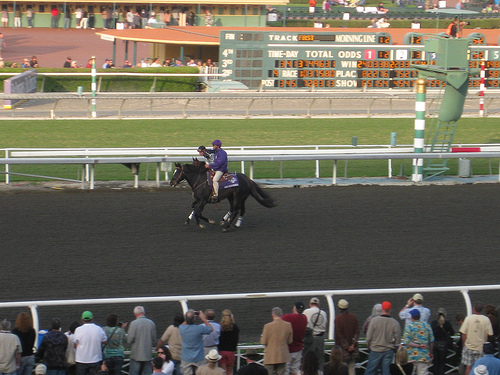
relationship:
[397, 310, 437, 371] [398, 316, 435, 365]
someone wearing shirt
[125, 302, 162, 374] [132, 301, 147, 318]
man with hair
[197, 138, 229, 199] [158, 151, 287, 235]
man riding horse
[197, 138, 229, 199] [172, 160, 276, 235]
man riding horses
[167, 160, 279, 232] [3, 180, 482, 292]
horse on track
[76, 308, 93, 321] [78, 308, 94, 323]
cap on man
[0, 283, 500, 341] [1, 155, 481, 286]
barricade at track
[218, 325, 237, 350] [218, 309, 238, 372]
shirt on woman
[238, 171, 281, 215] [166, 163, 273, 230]
tail on horse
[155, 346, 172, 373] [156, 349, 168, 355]
woman wearing glasses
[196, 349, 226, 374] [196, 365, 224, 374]
man wearing shirt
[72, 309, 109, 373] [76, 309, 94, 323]
man wearing cap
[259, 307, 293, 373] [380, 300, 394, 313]
man wearing cap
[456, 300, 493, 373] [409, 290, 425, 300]
man wearing cap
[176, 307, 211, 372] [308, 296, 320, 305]
man wearing cap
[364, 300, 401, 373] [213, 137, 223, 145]
man wearing cap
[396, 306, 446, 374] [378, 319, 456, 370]
man wearing shirt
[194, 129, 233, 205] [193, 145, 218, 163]
man wearing hoodie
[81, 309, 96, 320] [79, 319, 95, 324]
green hat worn on head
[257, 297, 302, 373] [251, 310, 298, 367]
gentleman in tan coat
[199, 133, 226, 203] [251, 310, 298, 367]
gentleman in tan coat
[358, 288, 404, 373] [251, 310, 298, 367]
gentleman in tan coat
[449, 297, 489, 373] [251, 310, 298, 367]
gentleman in tan coat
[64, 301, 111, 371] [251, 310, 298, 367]
gentleman in tan coat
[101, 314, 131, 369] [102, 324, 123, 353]
woman wearing crossbody bag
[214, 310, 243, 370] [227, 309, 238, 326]
woman with ponytail